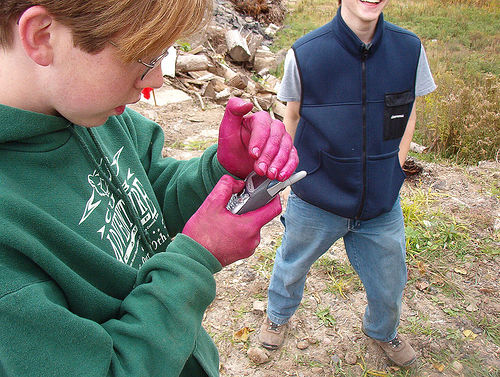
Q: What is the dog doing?
A: No dog.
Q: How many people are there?
A: Two.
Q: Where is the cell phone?
A: In boys hand.